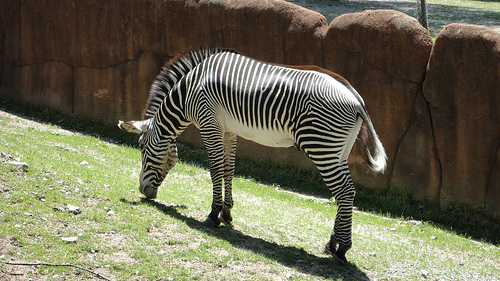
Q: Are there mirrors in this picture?
A: No, there are no mirrors.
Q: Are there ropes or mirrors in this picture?
A: No, there are no mirrors or ropes.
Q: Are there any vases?
A: No, there are no vases.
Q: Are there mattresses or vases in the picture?
A: No, there are no vases or mattresses.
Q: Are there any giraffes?
A: No, there are no giraffes.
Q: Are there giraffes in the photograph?
A: No, there are no giraffes.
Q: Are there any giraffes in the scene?
A: No, there are no giraffes.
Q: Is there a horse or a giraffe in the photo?
A: No, there are no giraffes or horses.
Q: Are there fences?
A: Yes, there is a fence.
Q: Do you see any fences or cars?
A: Yes, there is a fence.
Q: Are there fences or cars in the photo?
A: Yes, there is a fence.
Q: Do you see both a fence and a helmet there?
A: No, there is a fence but no helmets.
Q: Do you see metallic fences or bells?
A: Yes, there is a metal fence.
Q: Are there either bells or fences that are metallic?
A: Yes, the fence is metallic.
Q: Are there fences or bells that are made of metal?
A: Yes, the fence is made of metal.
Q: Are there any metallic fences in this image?
A: Yes, there is a metal fence.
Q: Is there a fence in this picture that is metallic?
A: Yes, there is a fence that is metallic.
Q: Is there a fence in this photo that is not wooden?
A: Yes, there is a metallic fence.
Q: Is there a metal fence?
A: Yes, there is a fence that is made of metal.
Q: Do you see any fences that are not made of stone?
A: Yes, there is a fence that is made of metal.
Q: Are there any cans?
A: No, there are no cans.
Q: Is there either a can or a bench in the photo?
A: No, there are no cans or benches.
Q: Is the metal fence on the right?
A: Yes, the fence is on the right of the image.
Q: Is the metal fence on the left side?
A: No, the fence is on the right of the image.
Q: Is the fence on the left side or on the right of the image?
A: The fence is on the right of the image.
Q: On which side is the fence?
A: The fence is on the right of the image.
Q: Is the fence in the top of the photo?
A: Yes, the fence is in the top of the image.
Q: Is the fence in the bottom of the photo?
A: No, the fence is in the top of the image.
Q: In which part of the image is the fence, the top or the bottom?
A: The fence is in the top of the image.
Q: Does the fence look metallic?
A: Yes, the fence is metallic.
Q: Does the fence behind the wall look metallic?
A: Yes, the fence is metallic.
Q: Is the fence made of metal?
A: Yes, the fence is made of metal.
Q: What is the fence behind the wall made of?
A: The fence is made of metal.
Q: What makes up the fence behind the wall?
A: The fence is made of metal.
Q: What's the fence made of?
A: The fence is made of metal.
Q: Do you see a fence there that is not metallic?
A: No, there is a fence but it is metallic.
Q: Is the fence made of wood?
A: No, the fence is made of metal.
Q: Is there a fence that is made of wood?
A: No, there is a fence but it is made of metal.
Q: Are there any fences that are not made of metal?
A: No, there is a fence but it is made of metal.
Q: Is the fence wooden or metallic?
A: The fence is metallic.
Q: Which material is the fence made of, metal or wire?
A: The fence is made of metal.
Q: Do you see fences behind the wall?
A: Yes, there is a fence behind the wall.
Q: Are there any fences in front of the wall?
A: No, the fence is behind the wall.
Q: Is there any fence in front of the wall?
A: No, the fence is behind the wall.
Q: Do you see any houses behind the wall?
A: No, there is a fence behind the wall.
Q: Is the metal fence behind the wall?
A: Yes, the fence is behind the wall.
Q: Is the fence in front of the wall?
A: No, the fence is behind the wall.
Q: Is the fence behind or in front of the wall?
A: The fence is behind the wall.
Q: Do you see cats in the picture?
A: No, there are no cats.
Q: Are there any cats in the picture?
A: No, there are no cats.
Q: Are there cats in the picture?
A: No, there are no cats.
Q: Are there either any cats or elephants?
A: No, there are no cats or elephants.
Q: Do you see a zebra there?
A: Yes, there is a zebra.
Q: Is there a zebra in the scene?
A: Yes, there is a zebra.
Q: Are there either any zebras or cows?
A: Yes, there is a zebra.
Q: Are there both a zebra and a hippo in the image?
A: No, there is a zebra but no hippoes.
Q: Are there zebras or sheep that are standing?
A: Yes, the zebra is standing.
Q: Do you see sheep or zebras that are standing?
A: Yes, the zebra is standing.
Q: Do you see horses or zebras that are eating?
A: Yes, the zebra is eating.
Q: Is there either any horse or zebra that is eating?
A: Yes, the zebra is eating.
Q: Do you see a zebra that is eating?
A: Yes, there is a zebra that is eating.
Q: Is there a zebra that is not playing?
A: Yes, there is a zebra that is eating.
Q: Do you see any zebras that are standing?
A: Yes, there is a zebra that is standing.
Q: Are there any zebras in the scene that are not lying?
A: Yes, there is a zebra that is standing.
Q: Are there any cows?
A: No, there are no cows.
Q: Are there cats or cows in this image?
A: No, there are no cows or cats.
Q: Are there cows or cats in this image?
A: No, there are no cows or cats.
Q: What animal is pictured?
A: The animal is a zebra.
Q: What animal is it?
A: The animal is a zebra.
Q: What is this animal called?
A: This is a zebra.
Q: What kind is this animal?
A: This is a zebra.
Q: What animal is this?
A: This is a zebra.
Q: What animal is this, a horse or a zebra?
A: This is a zebra.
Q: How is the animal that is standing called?
A: The animal is a zebra.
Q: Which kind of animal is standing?
A: The animal is a zebra.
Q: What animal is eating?
A: The animal is a zebra.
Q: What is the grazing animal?
A: The animal is a zebra.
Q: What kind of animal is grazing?
A: The animal is a zebra.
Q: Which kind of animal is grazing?
A: The animal is a zebra.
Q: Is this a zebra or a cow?
A: This is a zebra.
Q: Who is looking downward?
A: The zebra is looking downward.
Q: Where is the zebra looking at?
A: The zebra is looking downward.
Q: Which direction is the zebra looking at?
A: The zebra is looking downward.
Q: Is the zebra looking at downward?
A: Yes, the zebra is looking downward.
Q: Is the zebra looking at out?
A: No, the zebra is looking downward.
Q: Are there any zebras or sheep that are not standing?
A: No, there is a zebra but it is standing.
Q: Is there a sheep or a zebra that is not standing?
A: No, there is a zebra but it is standing.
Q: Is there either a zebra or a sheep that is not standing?
A: No, there is a zebra but it is standing.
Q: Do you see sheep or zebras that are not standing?
A: No, there is a zebra but it is standing.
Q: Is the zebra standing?
A: Yes, the zebra is standing.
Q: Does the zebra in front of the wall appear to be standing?
A: Yes, the zebra is standing.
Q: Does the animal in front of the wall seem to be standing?
A: Yes, the zebra is standing.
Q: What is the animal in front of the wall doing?
A: The zebra is standing.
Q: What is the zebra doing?
A: The zebra is standing.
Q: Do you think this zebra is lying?
A: No, the zebra is standing.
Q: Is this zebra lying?
A: No, the zebra is standing.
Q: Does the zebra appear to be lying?
A: No, the zebra is standing.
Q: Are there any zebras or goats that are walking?
A: No, there is a zebra but it is standing.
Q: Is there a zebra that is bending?
A: No, there is a zebra but it is standing.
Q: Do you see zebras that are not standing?
A: No, there is a zebra but it is standing.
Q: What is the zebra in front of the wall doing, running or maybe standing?
A: The zebra is standing.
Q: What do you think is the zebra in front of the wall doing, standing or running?
A: The zebra is standing.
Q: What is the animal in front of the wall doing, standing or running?
A: The zebra is standing.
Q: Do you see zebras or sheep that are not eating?
A: No, there is a zebra but it is eating.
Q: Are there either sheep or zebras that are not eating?
A: No, there is a zebra but it is eating.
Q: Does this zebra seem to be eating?
A: Yes, the zebra is eating.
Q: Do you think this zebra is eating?
A: Yes, the zebra is eating.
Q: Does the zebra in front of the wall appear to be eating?
A: Yes, the zebra is eating.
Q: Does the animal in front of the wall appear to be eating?
A: Yes, the zebra is eating.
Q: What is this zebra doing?
A: The zebra is eating.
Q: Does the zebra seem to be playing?
A: No, the zebra is eating.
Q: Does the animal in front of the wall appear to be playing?
A: No, the zebra is eating.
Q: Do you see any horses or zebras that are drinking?
A: No, there is a zebra but it is eating.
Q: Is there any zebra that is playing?
A: No, there is a zebra but it is eating.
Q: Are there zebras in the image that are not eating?
A: No, there is a zebra but it is eating.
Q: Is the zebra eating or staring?
A: The zebra is eating.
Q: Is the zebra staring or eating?
A: The zebra is eating.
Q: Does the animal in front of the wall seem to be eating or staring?
A: The zebra is eating.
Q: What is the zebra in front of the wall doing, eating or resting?
A: The zebra is eating.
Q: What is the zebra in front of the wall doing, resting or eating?
A: The zebra is eating.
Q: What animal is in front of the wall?
A: The zebra is in front of the wall.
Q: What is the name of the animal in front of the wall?
A: The animal is a zebra.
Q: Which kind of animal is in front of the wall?
A: The animal is a zebra.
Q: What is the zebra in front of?
A: The zebra is in front of the wall.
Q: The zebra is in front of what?
A: The zebra is in front of the wall.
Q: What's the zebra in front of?
A: The zebra is in front of the wall.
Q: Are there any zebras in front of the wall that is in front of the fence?
A: Yes, there is a zebra in front of the wall.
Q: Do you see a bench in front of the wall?
A: No, there is a zebra in front of the wall.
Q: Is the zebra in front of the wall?
A: Yes, the zebra is in front of the wall.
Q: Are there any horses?
A: No, there are no horses.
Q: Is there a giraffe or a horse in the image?
A: No, there are no horses or giraffes.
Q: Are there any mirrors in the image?
A: No, there are no mirrors.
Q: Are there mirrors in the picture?
A: No, there are no mirrors.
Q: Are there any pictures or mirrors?
A: No, there are no mirrors or pictures.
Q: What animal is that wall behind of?
A: The wall is behind the zebra.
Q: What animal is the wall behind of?
A: The wall is behind the zebra.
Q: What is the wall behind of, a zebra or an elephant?
A: The wall is behind a zebra.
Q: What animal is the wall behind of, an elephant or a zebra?
A: The wall is behind a zebra.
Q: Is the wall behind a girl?
A: No, the wall is behind a zebra.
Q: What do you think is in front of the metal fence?
A: The wall is in front of the fence.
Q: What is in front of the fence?
A: The wall is in front of the fence.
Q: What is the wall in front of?
A: The wall is in front of the fence.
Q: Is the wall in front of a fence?
A: Yes, the wall is in front of a fence.